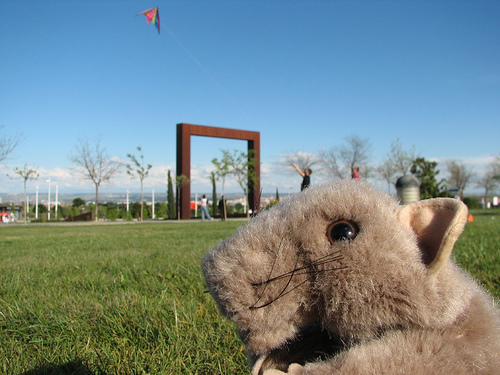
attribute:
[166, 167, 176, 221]
tree — tall, thin, pine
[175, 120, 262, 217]
frame — large, brown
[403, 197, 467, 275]
ear — brown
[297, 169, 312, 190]
top — black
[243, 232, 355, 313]
whiskers — black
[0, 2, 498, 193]
sky — blue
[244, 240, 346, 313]
whiskers — black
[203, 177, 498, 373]
plush — gray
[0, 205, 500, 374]
green field — empty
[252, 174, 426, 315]
animal — stuffed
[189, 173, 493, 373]
stuffed mouse — brown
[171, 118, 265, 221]
frame — brown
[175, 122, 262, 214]
desig — square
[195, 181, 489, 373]
animal — stuffed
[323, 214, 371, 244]
eye — plastic, brown, black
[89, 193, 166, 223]
trees — green